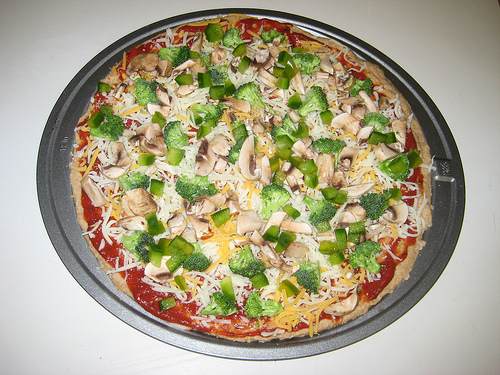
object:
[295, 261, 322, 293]
vegetable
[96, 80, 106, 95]
vegetable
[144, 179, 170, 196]
vegetable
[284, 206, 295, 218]
vegetable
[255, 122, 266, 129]
mushroom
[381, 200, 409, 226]
mushroom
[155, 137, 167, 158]
mushroom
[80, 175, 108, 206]
mushroom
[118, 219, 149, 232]
mushroom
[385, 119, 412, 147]
mushroom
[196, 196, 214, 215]
mushroom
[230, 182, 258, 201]
cheese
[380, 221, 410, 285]
tomato sauce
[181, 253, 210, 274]
vegatable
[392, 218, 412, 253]
cheese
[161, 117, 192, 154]
vegetable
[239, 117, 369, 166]
floor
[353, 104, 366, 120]
mushroom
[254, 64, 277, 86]
mushroom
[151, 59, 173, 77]
mushroom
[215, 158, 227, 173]
mushroom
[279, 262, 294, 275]
mushroom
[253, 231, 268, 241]
mushroom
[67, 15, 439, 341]
pizza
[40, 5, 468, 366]
pan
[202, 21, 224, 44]
vegetable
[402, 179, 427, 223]
cheese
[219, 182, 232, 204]
vegetable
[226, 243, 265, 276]
broccoli floret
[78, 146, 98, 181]
cheese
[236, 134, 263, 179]
mushroom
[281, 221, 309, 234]
mushroom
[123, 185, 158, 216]
mushroom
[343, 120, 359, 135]
mushroom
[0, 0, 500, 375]
platter/table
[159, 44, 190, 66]
broccoli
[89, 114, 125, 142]
broccoli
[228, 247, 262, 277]
broccoli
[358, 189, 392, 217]
broccoli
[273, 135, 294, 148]
bell pepper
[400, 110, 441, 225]
crust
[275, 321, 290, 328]
piece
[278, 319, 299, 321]
piece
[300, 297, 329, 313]
piece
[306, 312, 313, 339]
piece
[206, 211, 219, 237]
piece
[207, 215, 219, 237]
cheese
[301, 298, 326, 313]
cheese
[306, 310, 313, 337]
cheese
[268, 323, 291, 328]
cheese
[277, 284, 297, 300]
cheese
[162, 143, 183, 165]
vegetable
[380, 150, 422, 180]
green vegetable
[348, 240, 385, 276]
vegetable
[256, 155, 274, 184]
mushroom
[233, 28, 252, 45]
cheese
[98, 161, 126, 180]
mushroom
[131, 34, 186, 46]
red sauce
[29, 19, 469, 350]
platter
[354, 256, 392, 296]
sauce